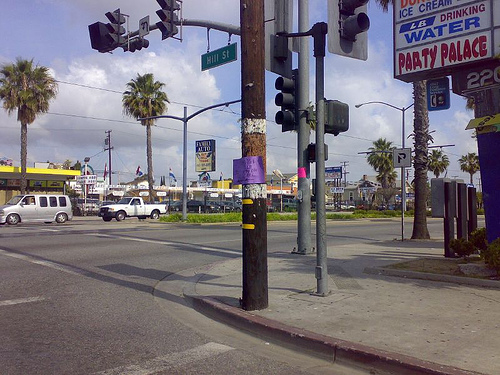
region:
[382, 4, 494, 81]
Street sign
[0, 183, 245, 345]
Not so busy intersection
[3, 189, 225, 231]
Two vehicles on the road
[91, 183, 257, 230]
White truck on the street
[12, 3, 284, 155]
Cloudy sky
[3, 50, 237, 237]
Palm trees on one side of the road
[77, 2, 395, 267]
Traffic signals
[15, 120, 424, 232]
Commercial properties in the background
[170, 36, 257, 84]
Green road sign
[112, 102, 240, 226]
Street light pole on the road divider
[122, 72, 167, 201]
tall palm tree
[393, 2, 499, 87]
shopping plaza sign with store names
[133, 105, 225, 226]
street lamp post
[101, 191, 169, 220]
white and black pickup truck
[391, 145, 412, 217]
metal black and white no parking sign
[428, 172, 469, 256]
telephone booths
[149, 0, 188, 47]
black hanging stoplight signal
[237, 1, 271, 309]
telephone pole with purple sign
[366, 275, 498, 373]
tan sidewalk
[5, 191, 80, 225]
silver and black passenger van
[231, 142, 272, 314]
a handwritten flyer on a telephone pole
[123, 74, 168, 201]
a tall palm tree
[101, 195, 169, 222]
a white truck driving on the road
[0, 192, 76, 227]
a silver van on the road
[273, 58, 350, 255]
a traffic signal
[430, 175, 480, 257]
public telephones on the sidewalk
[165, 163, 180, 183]
a flag flying in the background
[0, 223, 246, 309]
a crosswalk on the road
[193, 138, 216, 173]
an auto store's sign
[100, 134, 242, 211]
an auto dealer across the street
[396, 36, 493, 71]
a directional sign on street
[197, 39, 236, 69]
a directional sign on street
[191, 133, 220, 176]
a directional sign on street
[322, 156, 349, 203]
a directional sign on street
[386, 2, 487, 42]
a directional sign on street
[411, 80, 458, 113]
a directional sign on street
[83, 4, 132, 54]
traffic light in the street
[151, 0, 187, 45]
traffic light in the street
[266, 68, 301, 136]
traffic light in the street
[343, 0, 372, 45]
traffic light in the street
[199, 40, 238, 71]
green and white street sign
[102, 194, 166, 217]
white truck on street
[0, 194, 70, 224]
silver van on street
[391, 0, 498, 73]
sign with multiple logos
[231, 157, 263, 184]
purple sign on wood post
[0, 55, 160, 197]
palm trees across street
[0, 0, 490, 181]
puffy clouds in sky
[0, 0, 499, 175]
blue sky with puffy clouds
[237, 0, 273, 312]
wooden post with white and tan paint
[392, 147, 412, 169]
white and black no parking sign on street light